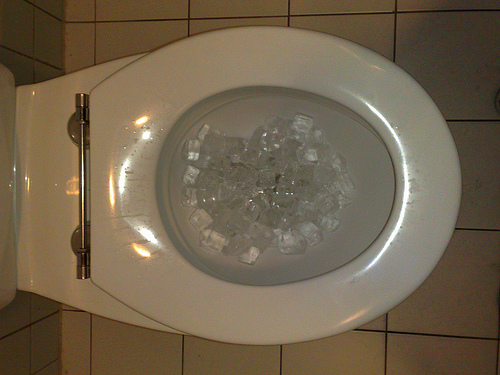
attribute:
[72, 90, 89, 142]
hinge — silver, metal 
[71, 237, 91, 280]
hinge — metal , silver 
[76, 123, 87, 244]
bar — metal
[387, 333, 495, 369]
tile — beige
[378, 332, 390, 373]
grout — brown, chocolate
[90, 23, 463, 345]
toilet seat — white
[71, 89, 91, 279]
hinge — metal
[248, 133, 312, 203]
ice — cubes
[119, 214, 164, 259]
glare — light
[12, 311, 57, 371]
wall — beige, tiled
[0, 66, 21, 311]
tank — holding, water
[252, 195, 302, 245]
ice — cube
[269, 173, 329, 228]
ice — fresh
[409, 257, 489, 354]
floor — tan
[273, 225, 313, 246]
ice — cold